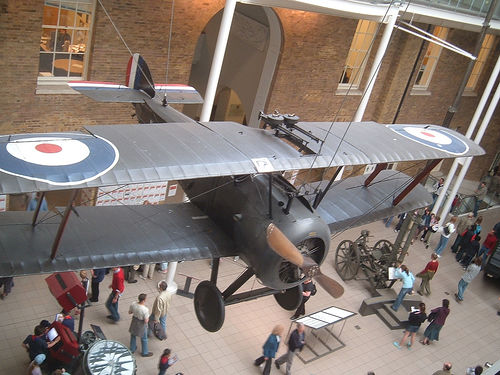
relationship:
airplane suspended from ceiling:
[8, 53, 494, 320] [272, 5, 386, 30]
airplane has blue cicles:
[8, 53, 494, 320] [3, 124, 118, 189]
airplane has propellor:
[8, 53, 494, 320] [264, 226, 352, 303]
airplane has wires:
[8, 53, 494, 320] [98, 6, 137, 51]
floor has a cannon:
[367, 334, 399, 363] [337, 233, 401, 284]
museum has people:
[4, 6, 498, 375] [87, 291, 174, 361]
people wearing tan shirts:
[87, 291, 174, 361] [132, 303, 170, 319]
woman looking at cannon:
[394, 262, 414, 312] [337, 233, 401, 284]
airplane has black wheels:
[8, 53, 494, 320] [190, 272, 229, 338]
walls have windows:
[7, 7, 32, 55] [39, 4, 91, 97]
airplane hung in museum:
[8, 53, 494, 320] [4, 6, 498, 375]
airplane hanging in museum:
[8, 53, 494, 320] [4, 6, 498, 375]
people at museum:
[87, 291, 174, 361] [4, 6, 498, 375]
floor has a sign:
[367, 334, 399, 363] [301, 303, 349, 336]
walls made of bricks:
[7, 7, 32, 55] [13, 67, 25, 80]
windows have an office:
[39, 4, 91, 97] [51, 38, 81, 73]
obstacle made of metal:
[351, 236, 418, 325] [367, 259, 379, 275]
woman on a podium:
[394, 262, 414, 312] [367, 292, 416, 325]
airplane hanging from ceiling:
[8, 53, 494, 320] [272, 5, 386, 30]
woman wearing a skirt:
[397, 300, 426, 353] [406, 320, 422, 334]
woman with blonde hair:
[256, 323, 288, 373] [271, 324, 287, 337]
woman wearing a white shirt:
[437, 215, 459, 260] [440, 220, 456, 243]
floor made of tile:
[367, 334, 399, 363] [199, 343, 212, 359]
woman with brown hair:
[394, 262, 414, 312] [400, 263, 411, 277]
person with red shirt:
[105, 268, 124, 317] [107, 272, 131, 289]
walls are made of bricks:
[7, 7, 32, 55] [13, 67, 25, 80]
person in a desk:
[52, 25, 71, 50] [44, 41, 53, 58]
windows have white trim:
[39, 4, 91, 97] [41, 75, 76, 97]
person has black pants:
[294, 280, 314, 316] [297, 293, 312, 315]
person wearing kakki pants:
[278, 323, 303, 374] [278, 350, 299, 373]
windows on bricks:
[39, 4, 91, 97] [13, 67, 25, 80]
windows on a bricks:
[39, 4, 91, 97] [13, 67, 25, 80]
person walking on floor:
[455, 257, 479, 305] [367, 334, 399, 363]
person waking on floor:
[455, 257, 479, 305] [367, 334, 399, 363]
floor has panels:
[367, 334, 399, 363] [87, 340, 128, 373]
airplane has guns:
[8, 53, 494, 320] [260, 97, 321, 151]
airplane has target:
[8, 53, 494, 320] [389, 110, 470, 161]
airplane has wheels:
[8, 53, 494, 320] [198, 276, 310, 326]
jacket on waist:
[124, 317, 152, 340] [132, 312, 148, 324]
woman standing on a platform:
[394, 262, 414, 312] [377, 292, 403, 331]